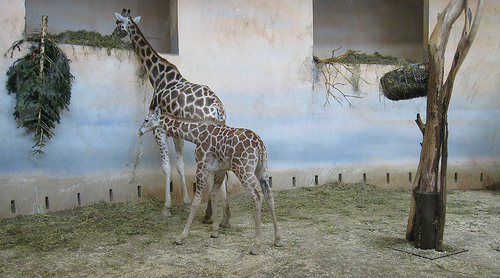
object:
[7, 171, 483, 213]
vertical lines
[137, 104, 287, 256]
giraffe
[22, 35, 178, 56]
shelf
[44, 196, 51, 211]
slits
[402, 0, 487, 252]
tree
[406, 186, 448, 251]
cylinder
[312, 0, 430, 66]
window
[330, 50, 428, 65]
straw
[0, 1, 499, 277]
enclosure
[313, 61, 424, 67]
ledge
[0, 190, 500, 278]
floor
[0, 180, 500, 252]
hay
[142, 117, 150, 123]
eye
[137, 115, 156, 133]
face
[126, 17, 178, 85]
neck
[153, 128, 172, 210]
leg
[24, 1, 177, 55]
opening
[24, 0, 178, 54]
hopper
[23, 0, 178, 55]
window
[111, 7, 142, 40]
head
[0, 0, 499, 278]
zoo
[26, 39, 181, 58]
ledge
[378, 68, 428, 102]
feeder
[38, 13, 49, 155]
branch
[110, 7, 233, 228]
giraffe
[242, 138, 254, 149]
spot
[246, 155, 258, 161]
spot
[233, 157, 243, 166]
spot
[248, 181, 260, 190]
spot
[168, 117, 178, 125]
spot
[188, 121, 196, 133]
spot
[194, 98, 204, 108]
spot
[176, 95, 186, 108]
spot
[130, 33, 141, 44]
spot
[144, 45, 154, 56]
spot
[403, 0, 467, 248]
pile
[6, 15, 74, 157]
tree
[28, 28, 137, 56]
hay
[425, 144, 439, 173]
wood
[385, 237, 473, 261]
plate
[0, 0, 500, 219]
wall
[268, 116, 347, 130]
paint